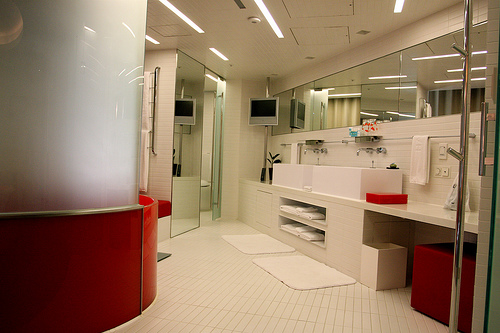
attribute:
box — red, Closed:
[368, 186, 405, 202]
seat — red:
[403, 234, 478, 331]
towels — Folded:
[280, 203, 325, 223]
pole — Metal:
[435, 0, 476, 327]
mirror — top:
[265, 45, 483, 133]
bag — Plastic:
[441, 170, 471, 215]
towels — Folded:
[273, 200, 320, 245]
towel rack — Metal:
[149, 56, 160, 163]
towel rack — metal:
[135, 67, 160, 205]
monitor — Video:
[244, 92, 284, 128]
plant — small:
[266, 143, 286, 165]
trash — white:
[356, 237, 408, 293]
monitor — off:
[246, 93, 281, 128]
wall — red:
[0, 206, 140, 331]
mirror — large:
[171, 51, 205, 178]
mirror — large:
[270, 21, 488, 136]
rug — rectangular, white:
[250, 249, 356, 295]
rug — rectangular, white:
[221, 231, 295, 256]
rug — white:
[251, 250, 354, 291]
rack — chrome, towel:
[282, 133, 475, 149]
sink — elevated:
[309, 163, 403, 201]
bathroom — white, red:
[2, 2, 494, 329]